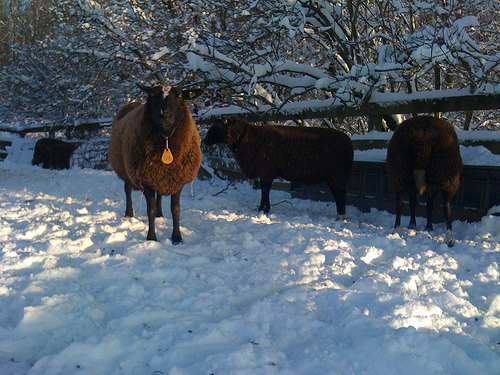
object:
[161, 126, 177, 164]
collar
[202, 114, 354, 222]
sheep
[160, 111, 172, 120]
nose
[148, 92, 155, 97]
eye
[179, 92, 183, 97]
eye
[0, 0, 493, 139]
trees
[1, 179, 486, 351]
snow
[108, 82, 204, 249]
board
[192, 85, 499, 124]
railing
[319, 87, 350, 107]
ground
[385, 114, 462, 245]
sheep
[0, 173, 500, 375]
reindeer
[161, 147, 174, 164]
tag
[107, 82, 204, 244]
sheep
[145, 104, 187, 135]
neck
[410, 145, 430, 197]
tail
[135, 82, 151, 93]
ear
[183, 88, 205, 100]
ear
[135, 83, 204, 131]
head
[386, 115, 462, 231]
backside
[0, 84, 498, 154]
fence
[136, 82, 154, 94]
antlers